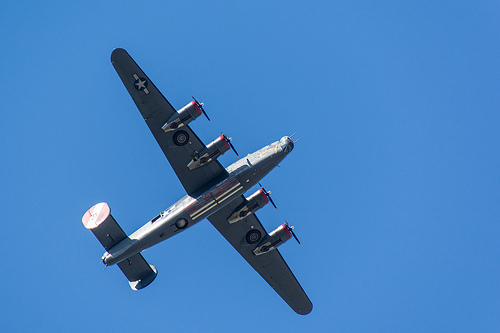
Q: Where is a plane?
A: In the air.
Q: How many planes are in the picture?
A: One.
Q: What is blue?
A: Sky.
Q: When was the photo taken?
A: Daytime.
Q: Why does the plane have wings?
A: To fly.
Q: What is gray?
A: The airplane.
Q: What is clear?
A: The sky.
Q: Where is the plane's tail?
A: On back of plane.